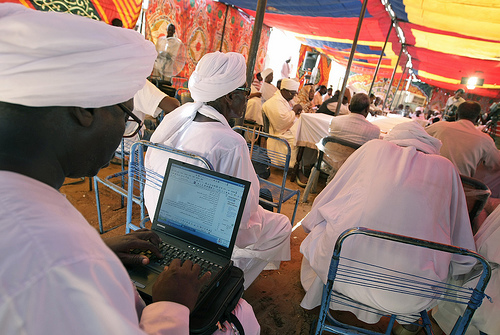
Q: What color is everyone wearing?
A: White.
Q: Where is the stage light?
A: Upper right corner.